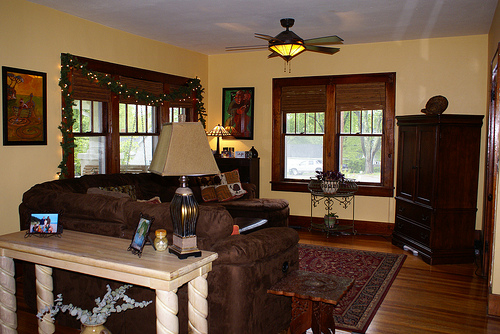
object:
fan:
[225, 18, 345, 73]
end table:
[266, 269, 355, 332]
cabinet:
[391, 114, 484, 268]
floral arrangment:
[36, 283, 153, 333]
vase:
[82, 321, 113, 331]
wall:
[208, 32, 488, 233]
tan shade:
[147, 122, 219, 176]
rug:
[291, 244, 407, 334]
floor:
[402, 284, 478, 333]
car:
[289, 159, 324, 175]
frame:
[222, 87, 255, 141]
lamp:
[148, 122, 221, 260]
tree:
[343, 116, 379, 169]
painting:
[224, 90, 251, 137]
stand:
[308, 177, 358, 239]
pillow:
[200, 169, 248, 202]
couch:
[19, 172, 300, 333]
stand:
[0, 229, 217, 333]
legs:
[154, 291, 179, 334]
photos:
[30, 214, 58, 233]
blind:
[336, 83, 386, 110]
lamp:
[206, 123, 231, 158]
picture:
[131, 217, 150, 250]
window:
[272, 78, 392, 187]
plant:
[315, 170, 347, 228]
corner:
[191, 52, 224, 74]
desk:
[214, 158, 260, 199]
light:
[270, 43, 306, 55]